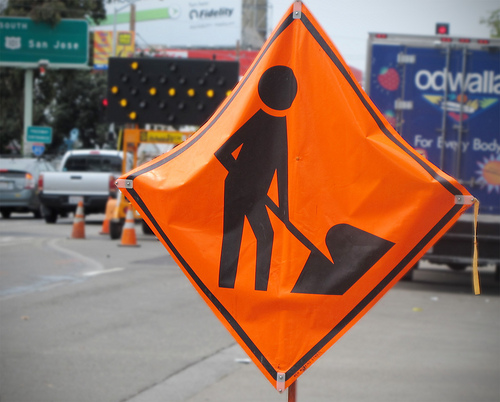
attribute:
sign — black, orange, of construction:
[118, 1, 477, 398]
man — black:
[211, 62, 308, 293]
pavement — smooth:
[5, 216, 499, 400]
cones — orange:
[68, 192, 161, 249]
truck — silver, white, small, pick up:
[40, 139, 128, 224]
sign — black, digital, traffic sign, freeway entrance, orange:
[108, 58, 236, 125]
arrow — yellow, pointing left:
[111, 61, 232, 118]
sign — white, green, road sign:
[2, 16, 89, 68]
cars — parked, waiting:
[2, 139, 132, 226]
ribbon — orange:
[468, 195, 486, 295]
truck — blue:
[365, 25, 499, 289]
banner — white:
[91, 3, 272, 47]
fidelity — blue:
[187, 7, 241, 22]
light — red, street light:
[434, 23, 452, 33]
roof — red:
[150, 48, 254, 78]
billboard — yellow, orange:
[88, 25, 134, 71]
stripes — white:
[69, 202, 137, 227]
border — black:
[128, 15, 465, 378]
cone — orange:
[118, 201, 142, 245]